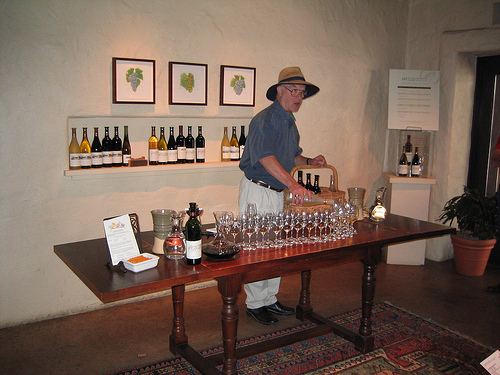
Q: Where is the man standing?
A: Behind a table.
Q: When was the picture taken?
A: During an event.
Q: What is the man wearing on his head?
A: A hat.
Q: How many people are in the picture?
A: One.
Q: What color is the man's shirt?
A: Blue.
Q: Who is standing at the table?
A: A man.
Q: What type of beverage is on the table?
A: Wine.